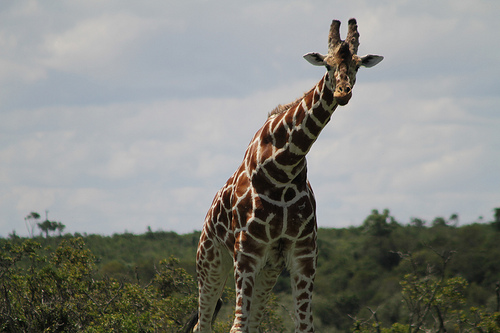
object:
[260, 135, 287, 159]
brown spot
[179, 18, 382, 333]
brown giraffe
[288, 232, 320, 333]
leg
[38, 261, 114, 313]
green leaves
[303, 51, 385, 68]
two ears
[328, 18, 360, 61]
horns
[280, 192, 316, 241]
spot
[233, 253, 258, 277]
spot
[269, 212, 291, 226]
spot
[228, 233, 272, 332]
leg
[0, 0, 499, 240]
sky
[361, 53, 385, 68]
ear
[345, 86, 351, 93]
nostril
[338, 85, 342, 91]
nostril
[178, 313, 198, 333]
tail end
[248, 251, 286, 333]
legs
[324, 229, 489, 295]
grass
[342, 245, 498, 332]
tree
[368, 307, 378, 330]
branch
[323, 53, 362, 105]
face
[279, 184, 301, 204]
spot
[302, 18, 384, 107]
head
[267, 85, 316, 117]
mane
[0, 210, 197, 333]
bush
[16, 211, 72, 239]
tree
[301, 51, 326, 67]
ear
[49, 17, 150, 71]
cloud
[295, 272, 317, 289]
spots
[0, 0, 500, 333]
safari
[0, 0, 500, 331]
area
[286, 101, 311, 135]
spot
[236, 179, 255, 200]
spot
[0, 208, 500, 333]
wild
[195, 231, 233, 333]
legs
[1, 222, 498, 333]
grass field